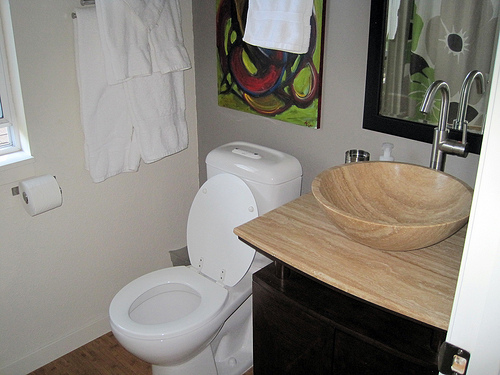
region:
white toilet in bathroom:
[107, 151, 271, 373]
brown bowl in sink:
[329, 162, 447, 260]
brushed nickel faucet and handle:
[410, 64, 467, 166]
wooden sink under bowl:
[242, 190, 456, 332]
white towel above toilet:
[230, 1, 329, 63]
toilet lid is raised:
[179, 162, 277, 285]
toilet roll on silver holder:
[19, 176, 69, 216]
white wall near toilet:
[72, 217, 163, 272]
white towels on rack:
[102, 3, 189, 192]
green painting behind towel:
[202, 8, 328, 140]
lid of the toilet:
[162, 162, 269, 285]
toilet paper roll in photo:
[6, 152, 83, 231]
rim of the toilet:
[92, 254, 220, 341]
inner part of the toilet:
[138, 284, 193, 325]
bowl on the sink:
[305, 156, 465, 252]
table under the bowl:
[256, 212, 326, 274]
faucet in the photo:
[390, 58, 490, 145]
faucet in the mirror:
[452, 62, 487, 119]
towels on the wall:
[53, 21, 204, 186]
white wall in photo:
[92, 184, 172, 241]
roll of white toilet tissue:
[10, 153, 87, 224]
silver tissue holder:
[4, 160, 81, 232]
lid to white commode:
[156, 175, 281, 287]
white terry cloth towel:
[77, 11, 154, 196]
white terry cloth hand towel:
[82, 3, 144, 89]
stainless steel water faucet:
[396, 61, 493, 183]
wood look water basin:
[301, 141, 476, 263]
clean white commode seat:
[92, 269, 229, 356]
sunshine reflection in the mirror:
[429, 22, 477, 61]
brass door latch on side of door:
[418, 334, 476, 374]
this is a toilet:
[94, 107, 293, 372]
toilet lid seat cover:
[172, 155, 287, 299]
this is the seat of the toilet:
[106, 247, 242, 372]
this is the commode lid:
[205, 122, 297, 201]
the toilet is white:
[83, 127, 320, 369]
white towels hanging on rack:
[63, 7, 225, 228]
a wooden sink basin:
[297, 133, 477, 276]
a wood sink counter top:
[223, 156, 470, 348]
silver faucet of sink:
[375, 37, 489, 224]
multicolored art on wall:
[203, 1, 360, 130]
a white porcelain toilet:
[109, 139, 301, 374]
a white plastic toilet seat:
[108, 173, 258, 339]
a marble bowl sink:
[312, 161, 474, 250]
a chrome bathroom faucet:
[418, 79, 468, 171]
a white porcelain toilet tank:
[203, 139, 300, 264]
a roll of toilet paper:
[19, 173, 60, 213]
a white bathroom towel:
[68, 1, 192, 183]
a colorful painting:
[214, 0, 326, 130]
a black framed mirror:
[363, 0, 499, 155]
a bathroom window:
[0, 0, 32, 167]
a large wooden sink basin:
[308, 166, 471, 253]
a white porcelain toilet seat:
[103, 268, 224, 335]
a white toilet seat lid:
[182, 169, 262, 286]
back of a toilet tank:
[201, 138, 301, 263]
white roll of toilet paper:
[18, 180, 65, 218]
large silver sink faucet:
[422, 76, 467, 173]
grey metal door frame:
[433, 339, 473, 372]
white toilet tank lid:
[199, 139, 304, 184]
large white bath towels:
[68, 8, 197, 185]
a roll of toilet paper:
[17, 170, 57, 209]